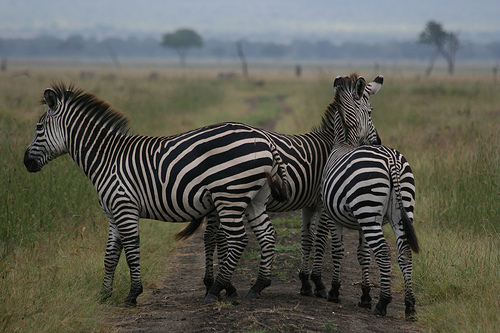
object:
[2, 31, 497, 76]
forested area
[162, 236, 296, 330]
road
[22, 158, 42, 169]
nose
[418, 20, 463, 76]
tree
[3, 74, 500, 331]
grass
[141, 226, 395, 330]
dirt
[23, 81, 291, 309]
zebra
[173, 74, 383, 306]
zebra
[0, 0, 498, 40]
sky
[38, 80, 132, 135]
mane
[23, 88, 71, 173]
head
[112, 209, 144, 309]
leg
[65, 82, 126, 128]
short hairs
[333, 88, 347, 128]
short hairs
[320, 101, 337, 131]
short hairs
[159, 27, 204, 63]
tree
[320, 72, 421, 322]
zebra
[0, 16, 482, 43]
clouds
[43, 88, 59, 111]
ear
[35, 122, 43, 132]
eye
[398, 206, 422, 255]
tail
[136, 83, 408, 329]
path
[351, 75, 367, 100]
ears